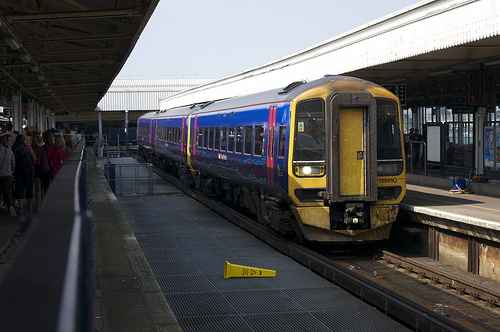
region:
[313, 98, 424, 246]
the door is yellow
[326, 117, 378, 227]
the door is yellow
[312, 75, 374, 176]
the door is yellow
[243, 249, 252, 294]
the cone is yellow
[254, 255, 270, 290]
the cone is yellow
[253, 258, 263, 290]
the cone is yellow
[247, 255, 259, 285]
the cone is yellow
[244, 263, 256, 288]
the cone is yellow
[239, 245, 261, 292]
the cone is yellow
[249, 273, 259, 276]
the cone is yellow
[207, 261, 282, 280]
yellow cone on ground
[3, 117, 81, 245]
people waiting on platform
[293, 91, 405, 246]
yellow front of train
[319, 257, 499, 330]
train tracks where train travels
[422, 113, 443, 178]
white sign on platform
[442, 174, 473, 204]
blue item on left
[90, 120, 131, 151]
gate in back of photo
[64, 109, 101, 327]
railing seperating passengers from train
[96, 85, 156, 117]
white awning over the top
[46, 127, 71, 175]
lady in red jacket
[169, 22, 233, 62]
this is the sky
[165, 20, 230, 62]
the sky is blue in color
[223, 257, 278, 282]
this is a cone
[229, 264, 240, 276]
the cone is yellow in color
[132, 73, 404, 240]
this is a train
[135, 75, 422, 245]
the train is long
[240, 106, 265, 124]
the train is blue in color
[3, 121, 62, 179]
these are several people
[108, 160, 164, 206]
the pavement is wet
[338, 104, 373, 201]
this is a door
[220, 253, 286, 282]
Safety pylon laying on the side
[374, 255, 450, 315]
Tracks used by the train to travel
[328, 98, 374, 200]
Access door on front of train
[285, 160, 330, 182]
Headlight on front of train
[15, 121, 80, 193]
Travelers waiting to board a train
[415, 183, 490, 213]
Shadow cast on ground by train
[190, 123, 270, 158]
Windows in the side of a passenger train car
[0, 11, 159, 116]
Roof to shelter of travelers from weather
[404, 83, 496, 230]
Loading area at train station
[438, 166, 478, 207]
Abandoned bag laying on the ground